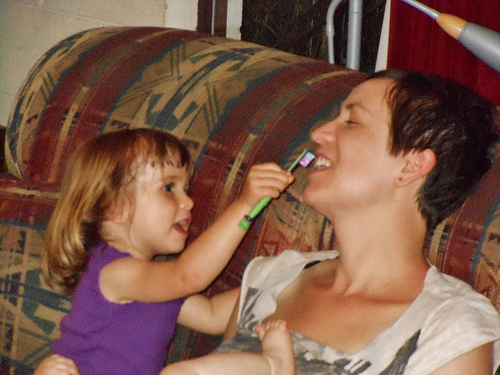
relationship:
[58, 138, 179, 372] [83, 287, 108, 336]
girl has shirt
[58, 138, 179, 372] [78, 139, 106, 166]
girl has hair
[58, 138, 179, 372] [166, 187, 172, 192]
girl has eye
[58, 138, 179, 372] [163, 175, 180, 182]
girl has eyebrow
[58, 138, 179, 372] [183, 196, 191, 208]
girl has nose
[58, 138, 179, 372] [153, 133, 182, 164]
girl has bangs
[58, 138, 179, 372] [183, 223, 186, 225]
girl has teeth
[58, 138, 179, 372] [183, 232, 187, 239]
girl has lip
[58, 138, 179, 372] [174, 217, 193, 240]
girl has mouth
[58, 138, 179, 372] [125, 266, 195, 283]
girl has arm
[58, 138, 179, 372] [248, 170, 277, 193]
girl has hand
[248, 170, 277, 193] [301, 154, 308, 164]
hand has toothbrush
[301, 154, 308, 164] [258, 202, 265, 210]
toothbrush has handle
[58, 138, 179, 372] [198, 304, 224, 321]
girl has arm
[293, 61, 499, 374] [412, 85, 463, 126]
woman has hair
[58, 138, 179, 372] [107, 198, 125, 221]
girl has ear